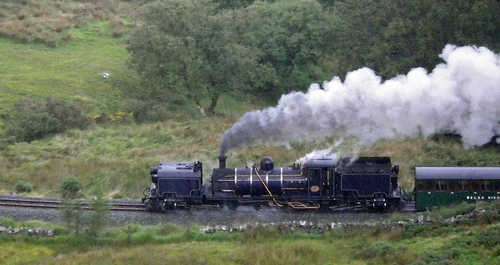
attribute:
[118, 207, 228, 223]
gravel — grey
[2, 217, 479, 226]
fence — rock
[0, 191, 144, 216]
train tracks — metal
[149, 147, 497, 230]
train — passenger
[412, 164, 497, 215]
car — green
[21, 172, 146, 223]
track — brown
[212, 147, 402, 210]
engine — train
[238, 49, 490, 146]
steam — white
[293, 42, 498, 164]
steam — white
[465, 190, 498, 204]
letters — white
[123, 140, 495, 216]
train — green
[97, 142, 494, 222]
train — black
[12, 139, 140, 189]
pasture fields — green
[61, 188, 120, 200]
steam — white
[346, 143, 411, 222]
bin — coal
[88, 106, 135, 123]
flowers — yellow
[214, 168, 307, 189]
banding — gold